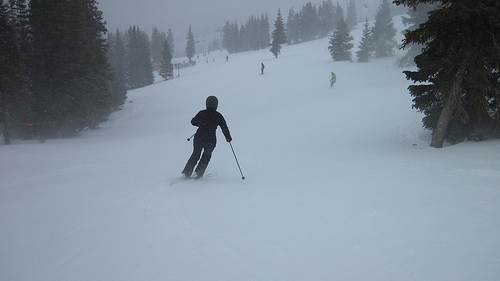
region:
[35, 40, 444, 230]
this is a ski slope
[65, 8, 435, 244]
the weather is stormy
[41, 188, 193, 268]
the ground is covered in snow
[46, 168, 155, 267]
the snow is bright white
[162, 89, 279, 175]
this is a skier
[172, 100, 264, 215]
the skier has ski poles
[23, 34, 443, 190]
this is winter time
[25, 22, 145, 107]
this area is forested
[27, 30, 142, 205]
these are evergreen trees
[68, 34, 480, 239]
it is very cold here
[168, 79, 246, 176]
skier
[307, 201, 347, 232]
white snow on hill side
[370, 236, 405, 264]
white snow on hill side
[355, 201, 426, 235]
white snow on hill side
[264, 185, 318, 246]
white snow on hill side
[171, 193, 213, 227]
white snow on hill side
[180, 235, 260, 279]
white snow on hill side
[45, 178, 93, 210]
white snow on hill side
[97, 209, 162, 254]
white snow on hill side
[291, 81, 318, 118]
white snow on hill side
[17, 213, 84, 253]
snow on a field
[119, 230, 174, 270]
snow on a field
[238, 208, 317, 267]
snow on a field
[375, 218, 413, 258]
snow on a field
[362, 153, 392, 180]
snow on a field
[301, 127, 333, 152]
snow on a field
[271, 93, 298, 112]
snow on a field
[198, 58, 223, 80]
snow on a field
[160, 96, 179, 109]
snow on a field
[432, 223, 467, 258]
snow on a field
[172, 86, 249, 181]
skier on ski slope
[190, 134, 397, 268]
thick white snow on slope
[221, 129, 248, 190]
ski pole in skier's hand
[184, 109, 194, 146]
ski pole in skier's hand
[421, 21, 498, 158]
trees growing on right of slope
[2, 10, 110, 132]
trees growing on left of slope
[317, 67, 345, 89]
skier on ski slope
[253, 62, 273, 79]
skier on ski slope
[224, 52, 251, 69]
skier on ski slope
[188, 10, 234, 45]
ski lift in the distance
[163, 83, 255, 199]
female skier with two poles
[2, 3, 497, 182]
many Christmas trees surrounding skiers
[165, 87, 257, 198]
female skier wearing black jacket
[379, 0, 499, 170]
tipping tree entrenched in the snow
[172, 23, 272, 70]
multitude of skiers skiing past big trees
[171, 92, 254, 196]
female skier wearing black pants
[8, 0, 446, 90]
gray sky over sea of trees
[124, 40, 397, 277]
pure white snow supporting groups of skiers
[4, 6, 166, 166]
faint shadows cast by tree lining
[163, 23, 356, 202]
female skier being left behind